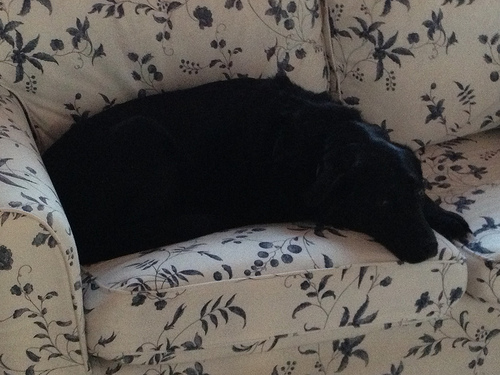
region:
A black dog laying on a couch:
[70, 76, 442, 264]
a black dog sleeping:
[36, 60, 422, 275]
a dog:
[52, 72, 449, 272]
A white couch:
[3, 0, 498, 355]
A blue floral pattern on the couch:
[4, 4, 494, 315]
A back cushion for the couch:
[11, 8, 326, 169]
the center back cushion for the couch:
[333, 5, 498, 137]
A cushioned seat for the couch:
[56, 162, 459, 344]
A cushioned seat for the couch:
[397, 152, 499, 285]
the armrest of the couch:
[0, 132, 81, 355]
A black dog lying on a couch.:
[43, 71, 470, 264]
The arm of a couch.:
[1, 86, 88, 374]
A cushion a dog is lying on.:
[77, 216, 470, 362]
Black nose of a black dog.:
[416, 234, 436, 256]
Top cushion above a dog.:
[1, 0, 333, 150]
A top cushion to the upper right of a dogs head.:
[320, 2, 499, 145]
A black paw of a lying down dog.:
[424, 195, 471, 247]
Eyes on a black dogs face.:
[373, 186, 426, 207]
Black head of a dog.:
[321, 126, 438, 263]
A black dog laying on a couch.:
[38, 76, 470, 261]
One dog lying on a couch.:
[0, 2, 494, 367]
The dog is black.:
[8, 94, 481, 262]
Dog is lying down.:
[36, 70, 477, 272]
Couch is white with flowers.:
[15, 1, 493, 366]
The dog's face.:
[312, 132, 454, 260]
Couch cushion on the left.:
[60, 233, 484, 338]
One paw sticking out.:
[425, 194, 482, 258]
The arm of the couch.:
[1, 68, 99, 370]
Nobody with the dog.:
[32, 3, 494, 370]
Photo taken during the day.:
[0, 6, 496, 367]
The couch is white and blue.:
[103, 255, 495, 347]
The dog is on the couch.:
[23, 65, 492, 290]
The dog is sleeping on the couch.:
[32, 73, 492, 304]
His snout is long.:
[386, 203, 455, 287]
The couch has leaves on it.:
[16, 9, 268, 89]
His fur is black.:
[20, 53, 473, 267]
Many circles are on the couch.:
[229, 234, 311, 286]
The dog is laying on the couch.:
[20, 44, 498, 324]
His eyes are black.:
[364, 171, 439, 219]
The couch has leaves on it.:
[119, 265, 471, 373]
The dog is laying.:
[57, 78, 472, 280]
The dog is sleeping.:
[57, 69, 469, 271]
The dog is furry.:
[30, 55, 451, 292]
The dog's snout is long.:
[375, 201, 465, 278]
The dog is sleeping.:
[37, 78, 478, 273]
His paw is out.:
[419, 178, 484, 265]